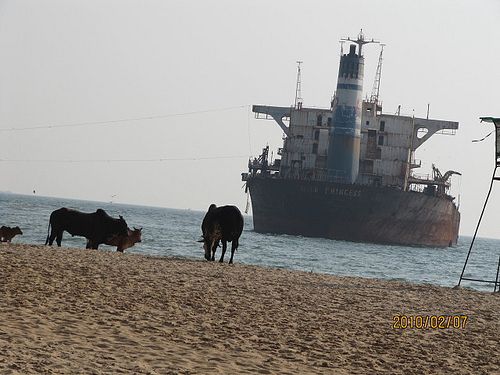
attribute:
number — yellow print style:
[383, 303, 481, 336]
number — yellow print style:
[389, 311, 470, 341]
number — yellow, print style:
[424, 308, 437, 338]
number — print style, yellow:
[434, 306, 446, 337]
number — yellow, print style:
[444, 309, 461, 337]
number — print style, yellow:
[456, 314, 476, 338]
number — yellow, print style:
[386, 310, 425, 330]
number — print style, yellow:
[425, 303, 454, 339]